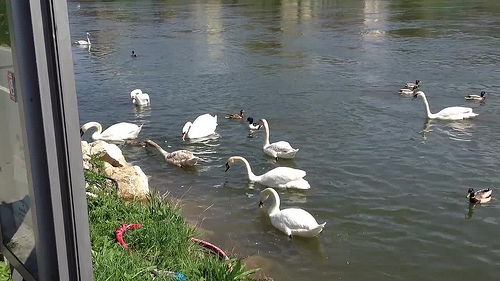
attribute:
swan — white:
[251, 183, 332, 247]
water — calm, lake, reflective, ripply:
[68, 0, 499, 280]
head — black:
[463, 188, 477, 201]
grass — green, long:
[84, 166, 251, 280]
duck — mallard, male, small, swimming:
[464, 184, 493, 204]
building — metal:
[1, 0, 96, 279]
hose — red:
[114, 222, 143, 261]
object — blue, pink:
[173, 270, 187, 280]